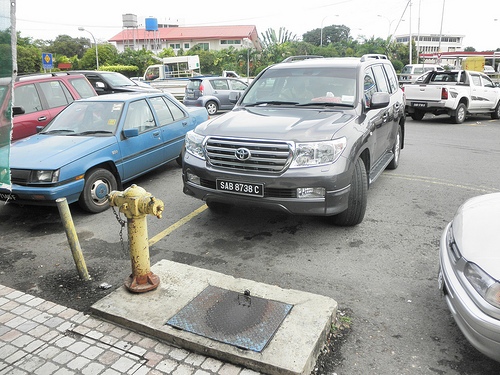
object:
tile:
[80, 345, 105, 359]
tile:
[1, 329, 22, 341]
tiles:
[25, 297, 45, 308]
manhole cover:
[164, 284, 294, 353]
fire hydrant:
[104, 183, 163, 292]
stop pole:
[54, 197, 92, 279]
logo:
[235, 147, 251, 161]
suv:
[183, 54, 405, 226]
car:
[0, 88, 211, 213]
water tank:
[122, 13, 138, 28]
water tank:
[145, 16, 158, 31]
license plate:
[216, 179, 264, 198]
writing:
[220, 182, 259, 194]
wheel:
[332, 156, 368, 226]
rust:
[127, 217, 136, 233]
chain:
[111, 207, 130, 256]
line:
[148, 203, 209, 248]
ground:
[0, 113, 499, 373]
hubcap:
[90, 180, 111, 206]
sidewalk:
[0, 282, 266, 375]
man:
[281, 79, 314, 100]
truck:
[402, 69, 500, 124]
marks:
[449, 91, 458, 98]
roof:
[107, 25, 255, 41]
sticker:
[341, 95, 355, 102]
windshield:
[242, 67, 358, 107]